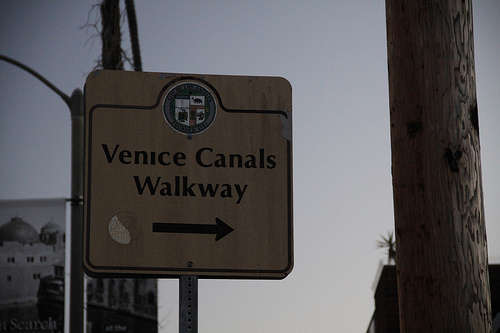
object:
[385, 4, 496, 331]
utility pole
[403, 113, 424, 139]
spot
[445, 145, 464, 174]
spot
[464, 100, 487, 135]
spot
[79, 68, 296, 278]
sign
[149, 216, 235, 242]
arrow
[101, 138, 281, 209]
venice canal walkway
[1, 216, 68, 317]
picture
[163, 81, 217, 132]
seal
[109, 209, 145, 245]
yin yang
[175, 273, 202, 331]
pole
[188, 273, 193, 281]
hole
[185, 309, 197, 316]
hole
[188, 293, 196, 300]
hole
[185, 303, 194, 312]
hole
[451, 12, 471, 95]
pattern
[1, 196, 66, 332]
banner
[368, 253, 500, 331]
building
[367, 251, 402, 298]
corner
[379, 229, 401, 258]
plant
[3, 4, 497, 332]
sky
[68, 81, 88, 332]
post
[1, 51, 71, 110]
extension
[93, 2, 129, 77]
tree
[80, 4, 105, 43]
twig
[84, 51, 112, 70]
twig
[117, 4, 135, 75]
twig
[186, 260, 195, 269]
bolt